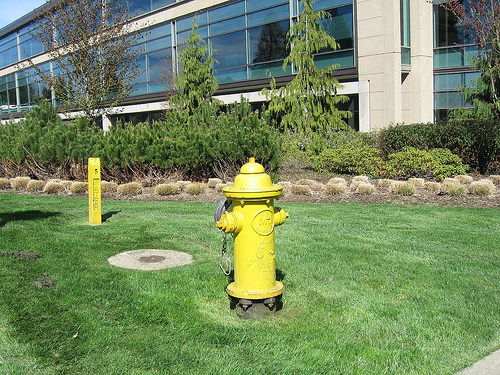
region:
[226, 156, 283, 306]
the fire hydrant is yellow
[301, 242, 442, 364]
the lawn is green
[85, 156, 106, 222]
the pole is yellow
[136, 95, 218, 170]
the shrubs are green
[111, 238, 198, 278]
the patch of cement is on the lawn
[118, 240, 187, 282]
the patch of cement is a circle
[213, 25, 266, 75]
the windows are glass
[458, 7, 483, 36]
the tree is red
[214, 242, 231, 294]
the chain is silver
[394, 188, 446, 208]
the dirt is brown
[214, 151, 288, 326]
yellow fire hydrant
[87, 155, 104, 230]
yellow post in the ground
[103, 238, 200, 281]
cement circle in the grass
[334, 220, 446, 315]
freshly mowed green grass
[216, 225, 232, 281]
silver chain on a firre hydrant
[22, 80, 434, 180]
a group of bushes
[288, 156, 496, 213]
small shrubs for landscaping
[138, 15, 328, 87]
a building with rows of windows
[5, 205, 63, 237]
a shadow on the grass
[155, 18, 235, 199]
medium sized pine tree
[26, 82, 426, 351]
a yellow fire hydrant on a green lawn in front of a large building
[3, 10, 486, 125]
a large building with tall windows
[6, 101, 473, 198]
green bushes and shrubs in the landscape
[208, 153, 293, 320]
the yellow fire hydrant on the lawn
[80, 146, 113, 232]
a yellow concrete post marker on the lawn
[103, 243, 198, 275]
access to the water line in the lawn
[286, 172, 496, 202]
small shrubs in the forefront of the landscape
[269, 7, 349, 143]
an evergreen tree in the landscape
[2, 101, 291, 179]
tall bushes in the landscaped area of the lawn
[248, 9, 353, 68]
reflections of the trees in the windows of the building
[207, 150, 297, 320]
a yellow fire hydrant on green grass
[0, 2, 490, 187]
a building with long windows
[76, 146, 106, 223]
a yellow pole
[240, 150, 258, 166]
a knob on top of fire hydrant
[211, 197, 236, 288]
a chain on fire hydrant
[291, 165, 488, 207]
small plants on the ground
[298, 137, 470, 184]
green bushes on soil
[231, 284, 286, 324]
gray base of fire hydrant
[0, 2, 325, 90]
winds with metal frames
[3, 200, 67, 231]
a black shadow on the grass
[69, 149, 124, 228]
Yellow post sticking out of grass.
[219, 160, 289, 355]
Yellow fire hydrant in grass.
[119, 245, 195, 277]
Cement circle in grassy area.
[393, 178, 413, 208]
Green bush in mulch.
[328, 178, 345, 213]
Green bush in mulch.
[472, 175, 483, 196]
Green bush in mulch.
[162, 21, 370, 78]
Windows a long building.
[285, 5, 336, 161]
Tall green tree in front of window.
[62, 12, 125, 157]
Tall tree in front of window.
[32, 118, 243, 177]
Green bushes in mulch area.